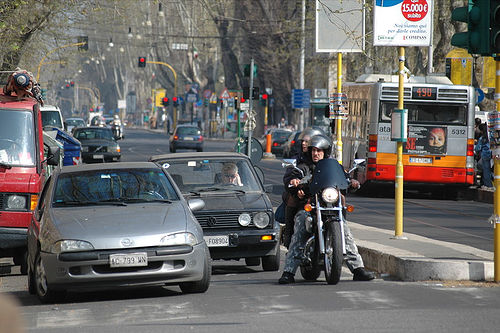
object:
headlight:
[254, 209, 270, 228]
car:
[146, 151, 281, 269]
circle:
[321, 188, 338, 203]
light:
[260, 90, 270, 107]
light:
[138, 54, 147, 69]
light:
[160, 97, 165, 106]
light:
[170, 96, 177, 107]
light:
[65, 82, 69, 86]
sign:
[371, 0, 434, 45]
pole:
[395, 48, 404, 106]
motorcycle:
[275, 157, 370, 284]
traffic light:
[260, 89, 272, 103]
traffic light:
[69, 80, 74, 87]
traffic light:
[89, 109, 95, 112]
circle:
[262, 94, 267, 99]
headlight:
[159, 230, 199, 245]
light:
[139, 59, 143, 69]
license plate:
[108, 251, 147, 266]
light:
[349, 207, 351, 212]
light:
[300, 203, 312, 212]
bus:
[330, 73, 476, 201]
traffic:
[0, 98, 499, 301]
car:
[27, 162, 213, 302]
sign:
[403, 125, 446, 156]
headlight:
[237, 212, 251, 227]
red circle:
[400, 1, 427, 21]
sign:
[289, 89, 311, 110]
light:
[155, 10, 163, 17]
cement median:
[343, 218, 498, 279]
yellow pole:
[393, 143, 403, 239]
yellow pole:
[334, 50, 344, 167]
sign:
[315, 1, 365, 53]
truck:
[0, 71, 57, 260]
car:
[169, 122, 205, 155]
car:
[67, 125, 122, 160]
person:
[217, 161, 242, 188]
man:
[276, 135, 373, 283]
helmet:
[305, 132, 332, 155]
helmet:
[296, 124, 328, 135]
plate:
[204, 234, 230, 247]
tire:
[32, 248, 46, 300]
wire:
[4, 26, 239, 56]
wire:
[104, 0, 181, 20]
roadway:
[6, 119, 498, 331]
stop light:
[170, 96, 178, 106]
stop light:
[161, 96, 169, 107]